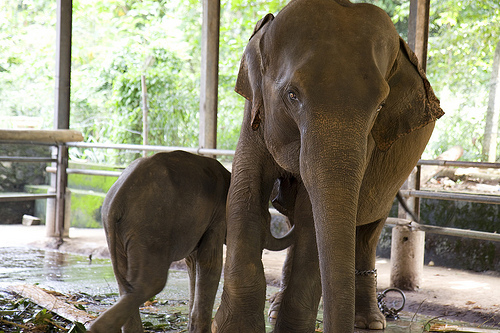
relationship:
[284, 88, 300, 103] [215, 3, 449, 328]
eye of elephant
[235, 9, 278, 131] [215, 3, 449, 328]
ear of elephant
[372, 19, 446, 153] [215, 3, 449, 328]
ear of elephant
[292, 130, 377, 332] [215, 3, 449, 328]
trunk of elephant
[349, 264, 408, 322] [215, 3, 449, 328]
chain attached to elephant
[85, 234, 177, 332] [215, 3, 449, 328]
legs of elephant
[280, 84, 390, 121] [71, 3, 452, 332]
eyes of elephants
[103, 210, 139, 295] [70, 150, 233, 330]
tail of elephant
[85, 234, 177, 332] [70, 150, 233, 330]
legs of elephant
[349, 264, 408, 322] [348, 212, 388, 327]
chain around leg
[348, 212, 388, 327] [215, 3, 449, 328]
leg of elephant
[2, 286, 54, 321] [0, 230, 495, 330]
leaves on ground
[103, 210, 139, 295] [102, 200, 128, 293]
tail of elephant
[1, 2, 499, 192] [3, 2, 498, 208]
trees in background